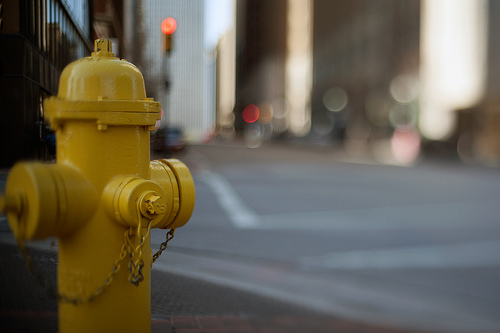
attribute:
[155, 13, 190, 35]
light — red, in distance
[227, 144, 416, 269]
lines — white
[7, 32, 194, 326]
fire hydrant — yellow, metal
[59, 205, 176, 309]
chain — yellow, hydrant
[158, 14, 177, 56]
traffic light — red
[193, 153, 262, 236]
line — white painted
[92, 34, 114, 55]
top — yellow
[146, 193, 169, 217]
bolt — large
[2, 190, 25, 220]
bolt — yellow